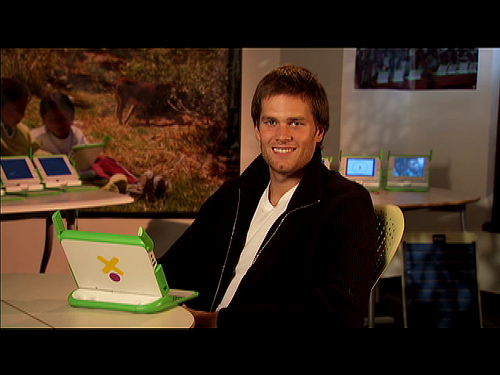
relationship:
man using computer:
[178, 66, 372, 375] [54, 215, 197, 314]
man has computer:
[178, 66, 372, 375] [54, 215, 197, 314]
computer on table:
[54, 215, 197, 314] [4, 218, 197, 334]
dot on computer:
[110, 274, 121, 283] [54, 215, 197, 314]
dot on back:
[110, 274, 121, 283] [65, 237, 161, 294]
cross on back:
[96, 255, 124, 271] [65, 237, 161, 294]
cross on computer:
[96, 255, 124, 271] [54, 215, 197, 314]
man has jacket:
[178, 66, 372, 375] [157, 148, 375, 373]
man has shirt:
[178, 66, 372, 375] [216, 179, 302, 306]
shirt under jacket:
[216, 179, 302, 306] [157, 148, 375, 373]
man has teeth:
[178, 66, 372, 375] [273, 148, 293, 153]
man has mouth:
[178, 66, 372, 375] [272, 144, 297, 158]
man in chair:
[178, 66, 372, 375] [368, 203, 403, 309]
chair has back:
[368, 203, 403, 309] [372, 200, 405, 323]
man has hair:
[178, 66, 372, 375] [251, 68, 331, 122]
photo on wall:
[4, 48, 240, 214] [3, 44, 343, 217]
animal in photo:
[110, 77, 179, 119] [4, 48, 240, 214]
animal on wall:
[110, 77, 179, 119] [3, 44, 343, 217]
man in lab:
[162, 66, 372, 375] [0, 50, 500, 374]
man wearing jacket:
[178, 66, 372, 375] [157, 148, 375, 373]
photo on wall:
[354, 40, 478, 89] [337, 39, 499, 144]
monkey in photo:
[418, 49, 441, 88] [354, 40, 478, 89]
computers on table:
[341, 151, 432, 185] [363, 190, 478, 203]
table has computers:
[363, 190, 478, 203] [341, 151, 432, 185]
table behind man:
[363, 190, 478, 203] [178, 66, 372, 375]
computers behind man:
[341, 151, 432, 185] [178, 66, 372, 375]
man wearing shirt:
[178, 66, 372, 375] [216, 179, 302, 306]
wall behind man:
[242, 49, 337, 165] [178, 66, 372, 375]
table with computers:
[363, 190, 478, 203] [341, 151, 432, 185]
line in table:
[3, 285, 53, 327] [4, 218, 197, 334]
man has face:
[162, 66, 372, 375] [259, 94, 308, 174]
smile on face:
[269, 143, 300, 153] [259, 94, 308, 174]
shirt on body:
[216, 179, 302, 306] [181, 186, 372, 371]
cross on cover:
[96, 255, 124, 271] [73, 241, 154, 296]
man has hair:
[162, 66, 372, 375] [251, 68, 331, 122]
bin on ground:
[404, 240, 484, 326] [367, 280, 499, 374]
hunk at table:
[203, 67, 363, 331] [4, 218, 197, 334]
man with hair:
[162, 66, 372, 375] [251, 65, 331, 122]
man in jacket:
[162, 66, 372, 375] [157, 148, 375, 373]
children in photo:
[3, 81, 80, 154] [4, 48, 230, 214]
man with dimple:
[178, 66, 372, 375] [281, 162, 285, 169]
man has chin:
[178, 66, 372, 375] [268, 154, 297, 175]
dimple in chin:
[281, 162, 285, 169] [268, 154, 297, 175]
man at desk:
[178, 66, 372, 375] [0, 211, 194, 328]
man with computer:
[178, 66, 372, 375] [64, 230, 196, 314]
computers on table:
[382, 151, 431, 192] [363, 190, 478, 203]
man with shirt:
[178, 66, 372, 375] [216, 179, 302, 306]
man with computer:
[178, 66, 372, 375] [54, 215, 197, 314]